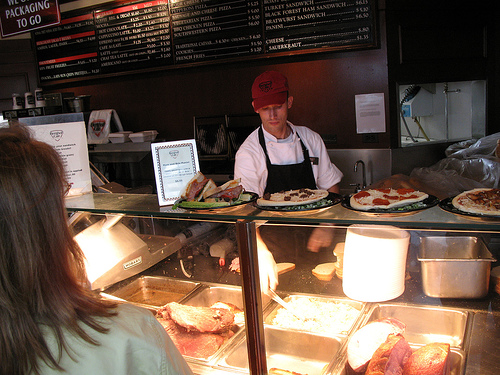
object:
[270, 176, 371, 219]
pizza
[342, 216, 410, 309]
plates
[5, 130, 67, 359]
hair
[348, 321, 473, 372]
pieces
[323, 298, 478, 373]
container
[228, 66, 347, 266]
employee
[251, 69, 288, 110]
cap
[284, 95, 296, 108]
ear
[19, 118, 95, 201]
list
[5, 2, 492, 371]
restaurant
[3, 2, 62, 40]
sign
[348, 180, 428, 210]
pizza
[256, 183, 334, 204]
pizza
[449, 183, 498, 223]
pizza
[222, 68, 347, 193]
man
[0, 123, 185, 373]
lady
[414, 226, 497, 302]
bin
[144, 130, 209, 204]
sign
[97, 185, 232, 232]
counter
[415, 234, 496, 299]
tub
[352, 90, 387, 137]
paper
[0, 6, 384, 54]
menu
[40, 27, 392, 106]
wall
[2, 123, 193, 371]
woman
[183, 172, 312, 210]
food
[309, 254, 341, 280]
bread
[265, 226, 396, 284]
counter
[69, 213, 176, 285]
slicer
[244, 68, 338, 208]
person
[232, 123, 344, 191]
shirt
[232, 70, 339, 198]
person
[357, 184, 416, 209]
pepperoni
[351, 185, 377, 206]
pizza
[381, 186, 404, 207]
pepperoni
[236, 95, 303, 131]
head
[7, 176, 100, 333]
hair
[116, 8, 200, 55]
menu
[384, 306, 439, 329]
pan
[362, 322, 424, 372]
meat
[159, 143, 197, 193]
writing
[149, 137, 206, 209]
paper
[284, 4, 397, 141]
wall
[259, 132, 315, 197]
apron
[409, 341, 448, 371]
food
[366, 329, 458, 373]
dish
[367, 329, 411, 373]
food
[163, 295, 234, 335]
dish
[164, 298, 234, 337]
food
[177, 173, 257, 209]
dish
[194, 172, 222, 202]
food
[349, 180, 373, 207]
food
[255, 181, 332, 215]
dish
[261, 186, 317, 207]
food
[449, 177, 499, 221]
dish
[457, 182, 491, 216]
food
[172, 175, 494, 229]
plates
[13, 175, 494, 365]
countertop